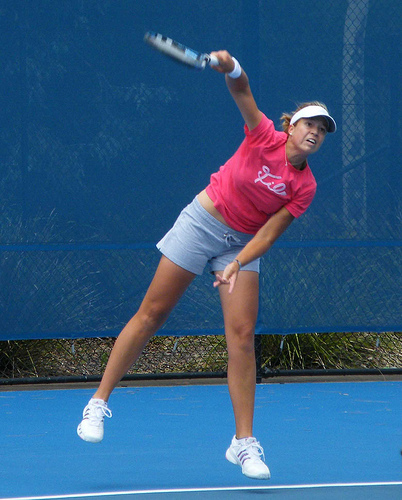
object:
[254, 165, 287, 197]
letters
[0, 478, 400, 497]
white line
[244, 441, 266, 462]
laces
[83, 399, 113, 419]
laces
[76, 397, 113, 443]
shoe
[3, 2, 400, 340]
divider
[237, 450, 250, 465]
stripes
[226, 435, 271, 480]
shoe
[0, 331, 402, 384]
fence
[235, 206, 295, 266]
arm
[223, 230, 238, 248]
string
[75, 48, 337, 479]
tennis player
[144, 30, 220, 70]
racket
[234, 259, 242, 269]
bracelet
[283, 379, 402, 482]
floor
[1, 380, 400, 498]
blue court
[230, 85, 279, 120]
wall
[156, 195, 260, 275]
shorts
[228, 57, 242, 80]
sweatband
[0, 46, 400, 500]
court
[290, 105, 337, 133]
visor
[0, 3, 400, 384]
fence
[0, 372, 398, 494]
tennis court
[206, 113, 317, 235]
shirt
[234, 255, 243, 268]
wrist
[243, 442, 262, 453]
pins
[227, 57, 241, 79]
armband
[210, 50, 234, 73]
hand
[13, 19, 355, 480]
tennis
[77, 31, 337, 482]
girl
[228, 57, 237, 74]
wrist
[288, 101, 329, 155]
head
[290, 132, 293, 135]
earring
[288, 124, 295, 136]
ear